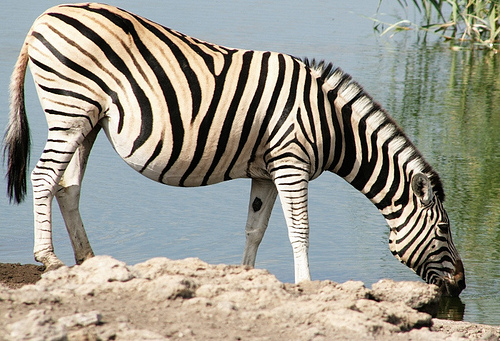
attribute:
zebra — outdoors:
[3, 0, 468, 301]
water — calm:
[2, 0, 500, 324]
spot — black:
[252, 196, 262, 212]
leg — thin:
[243, 178, 279, 265]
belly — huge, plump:
[99, 108, 269, 187]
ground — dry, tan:
[1, 256, 499, 340]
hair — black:
[5, 120, 31, 205]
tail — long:
[0, 27, 35, 203]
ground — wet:
[1, 262, 46, 289]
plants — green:
[371, 1, 499, 54]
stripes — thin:
[274, 171, 309, 253]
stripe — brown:
[43, 22, 131, 101]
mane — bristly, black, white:
[304, 55, 444, 198]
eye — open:
[438, 222, 450, 234]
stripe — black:
[328, 88, 343, 174]